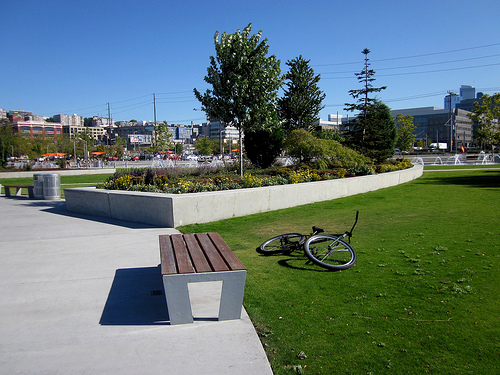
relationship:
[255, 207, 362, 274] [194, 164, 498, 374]
bicycle on floor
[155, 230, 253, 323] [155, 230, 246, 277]
bench with seat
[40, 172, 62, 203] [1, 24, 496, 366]
garbage can at park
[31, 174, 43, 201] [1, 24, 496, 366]
garbage can at park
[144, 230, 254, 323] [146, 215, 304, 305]
bench at park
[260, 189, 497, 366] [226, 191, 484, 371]
grass on ground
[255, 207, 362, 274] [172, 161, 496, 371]
bicycle on grass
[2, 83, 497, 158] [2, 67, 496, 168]
buildings in background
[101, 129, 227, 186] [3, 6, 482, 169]
cars in background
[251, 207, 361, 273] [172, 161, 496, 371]
bicycle on grass